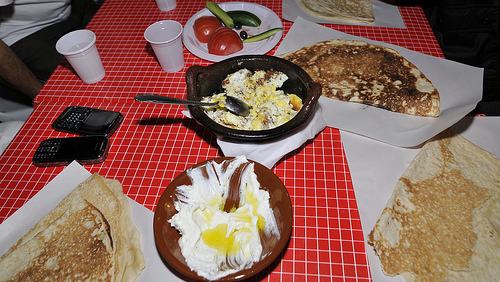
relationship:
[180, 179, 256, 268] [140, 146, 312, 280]
dipping sauce in plate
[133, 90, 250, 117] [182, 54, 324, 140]
spoon in skillet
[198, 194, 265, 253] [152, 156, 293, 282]
egg in plate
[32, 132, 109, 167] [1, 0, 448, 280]
phones on table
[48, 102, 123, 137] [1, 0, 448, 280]
phones on table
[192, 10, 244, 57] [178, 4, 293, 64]
tomato on plate